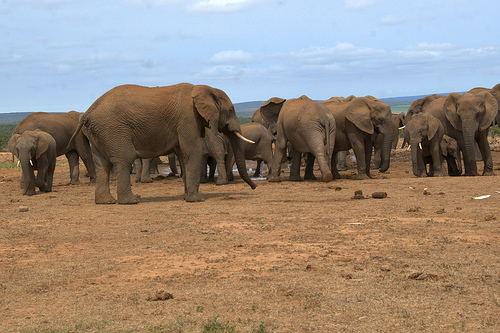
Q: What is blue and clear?
A: The sky.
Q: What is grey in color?
A: The elephant.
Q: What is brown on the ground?
A: The grass.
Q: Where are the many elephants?
A: On the ground.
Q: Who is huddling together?
A: Several elephants.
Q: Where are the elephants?
A: On the brown grass.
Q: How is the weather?
A: Cloudy.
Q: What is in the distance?
A: A mountain range.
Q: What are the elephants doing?
A: Standing on the grass.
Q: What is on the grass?
A: A herd of elephants.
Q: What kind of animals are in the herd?
A: Elephants.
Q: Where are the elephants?
A: In a herd standing on the grass.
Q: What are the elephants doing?
A: Standing.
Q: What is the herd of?
A: Elephants.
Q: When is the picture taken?
A: Daytime.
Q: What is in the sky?
A: Clouds.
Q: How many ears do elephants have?
A: Two.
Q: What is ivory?
A: The tusk.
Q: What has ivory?
A: Tusk.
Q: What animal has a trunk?
A: The elephant.